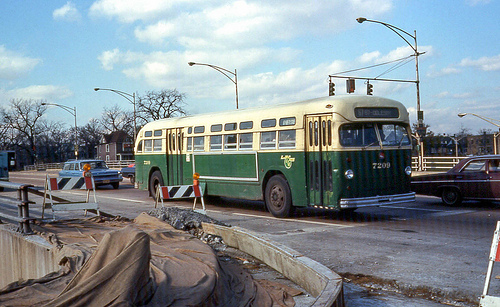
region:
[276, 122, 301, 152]
window on a gren and white bus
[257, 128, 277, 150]
window on a gren and white bus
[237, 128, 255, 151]
window on a gren and white bus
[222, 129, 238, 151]
window on a gren and white bus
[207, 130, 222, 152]
window on a gren and white bus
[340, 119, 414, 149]
window on a gren and white bus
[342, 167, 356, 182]
head light on a green and white bus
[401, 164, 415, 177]
head light on a green and white bus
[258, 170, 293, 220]
tire on a green and white bus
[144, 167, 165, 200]
tire on a green and white bus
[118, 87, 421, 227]
A green and white public bus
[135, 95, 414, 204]
a green and white bus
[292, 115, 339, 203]
the doors on a bus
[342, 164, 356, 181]
a circular headlight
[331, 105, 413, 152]
a bus's windshield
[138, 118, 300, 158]
windows on a bus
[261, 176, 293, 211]
wheel on a vehicle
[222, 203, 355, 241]
white line painted on the road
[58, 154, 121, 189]
a blue station wagon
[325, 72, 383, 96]
traffic lights on a pole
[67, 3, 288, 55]
white puffy clouds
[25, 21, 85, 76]
this is the sky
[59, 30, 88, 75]
the sky is blue in color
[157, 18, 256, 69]
the sky has clouds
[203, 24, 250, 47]
the clouds are white in color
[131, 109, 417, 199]
this is a bus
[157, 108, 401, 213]
the bus is big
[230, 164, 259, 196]
the bus is green in color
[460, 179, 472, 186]
the car is maroon in color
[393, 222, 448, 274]
this is the road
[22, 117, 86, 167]
these are some trees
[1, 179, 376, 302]
Roadwork in progress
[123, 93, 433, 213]
Green and beige bus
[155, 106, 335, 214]
Two doors on the side of the bus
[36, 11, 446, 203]
Street lights on the right side of the road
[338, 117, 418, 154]
Windshield and vipers in the front of the bus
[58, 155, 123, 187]
Blue car behind the bus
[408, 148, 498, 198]
Black car in front of the bus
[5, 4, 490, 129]
Blue sky with white clouds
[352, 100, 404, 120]
Bus route and number on the top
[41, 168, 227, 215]
Road blocks